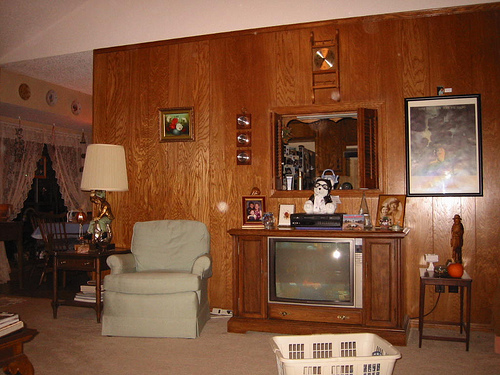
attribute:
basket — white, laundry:
[281, 323, 418, 374]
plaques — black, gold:
[236, 113, 251, 165]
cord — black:
[400, 289, 448, 334]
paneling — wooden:
[92, 1, 497, 333]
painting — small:
[157, 105, 195, 143]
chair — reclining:
[100, 217, 216, 337]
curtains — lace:
[6, 127, 101, 250]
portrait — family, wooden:
[242, 199, 262, 224]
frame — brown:
[238, 195, 267, 226]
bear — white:
[285, 172, 352, 217]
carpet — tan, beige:
[2, 292, 499, 374]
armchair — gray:
[86, 194, 248, 369]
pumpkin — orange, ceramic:
[449, 263, 464, 278]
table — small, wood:
[52, 216, 122, 310]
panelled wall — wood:
[93, 0, 498, 329]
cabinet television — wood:
[231, 229, 398, 329]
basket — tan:
[269, 330, 402, 374]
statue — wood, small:
[447, 212, 468, 267]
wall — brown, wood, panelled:
[154, 165, 210, 196]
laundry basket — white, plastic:
[269, 331, 402, 373]